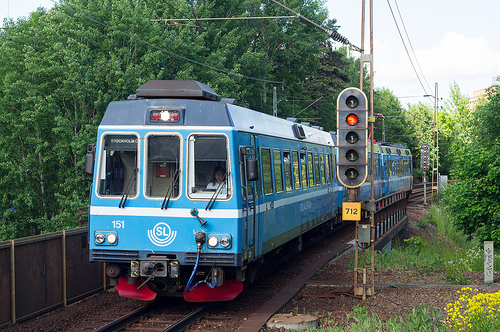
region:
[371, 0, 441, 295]
power lines suspended from pole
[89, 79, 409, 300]
front of blue commuter train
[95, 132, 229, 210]
windshield wipers on three windows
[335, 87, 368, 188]
glowing red light on panel of five circles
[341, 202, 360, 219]
three numbers on yellow square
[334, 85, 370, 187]
an electronic train signal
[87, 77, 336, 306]
a blue and white train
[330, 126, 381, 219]
a blue and white train car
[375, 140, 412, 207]
a blue and white train car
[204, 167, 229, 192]
a conductor in train engine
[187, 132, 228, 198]
a train front windshield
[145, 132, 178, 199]
a train front windshield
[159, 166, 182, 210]
a train windshield wiper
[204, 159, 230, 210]
a train windshield wiper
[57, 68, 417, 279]
this is a train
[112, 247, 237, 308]
the train is red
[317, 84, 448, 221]
the light is red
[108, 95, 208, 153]
the train has headlights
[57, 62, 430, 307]
this is a train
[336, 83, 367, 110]
this is a traffic light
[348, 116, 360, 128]
this is a traffic light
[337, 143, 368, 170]
this is a traffic light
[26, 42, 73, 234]
this is a tree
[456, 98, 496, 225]
this is a tree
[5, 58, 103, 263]
this is a tree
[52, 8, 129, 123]
this is a tree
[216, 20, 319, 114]
this is a tree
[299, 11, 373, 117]
this is a tree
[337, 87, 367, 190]
the traffic signal is showing red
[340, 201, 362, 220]
black color number on yellow board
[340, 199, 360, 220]
the numbers are painted on center of the board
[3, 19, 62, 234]
a tree in the woods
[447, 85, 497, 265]
a tree in the woods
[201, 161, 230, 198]
person operating the train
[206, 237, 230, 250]
headlight on the train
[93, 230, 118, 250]
headlight on the train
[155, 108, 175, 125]
headlight on the train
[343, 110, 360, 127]
red light on the signal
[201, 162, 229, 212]
windshield wiper on train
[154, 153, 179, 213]
windshield wiper on train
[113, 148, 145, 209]
windshield wiper on train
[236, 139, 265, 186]
mirror on the train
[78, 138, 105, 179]
mirror on the train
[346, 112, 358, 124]
the light is red